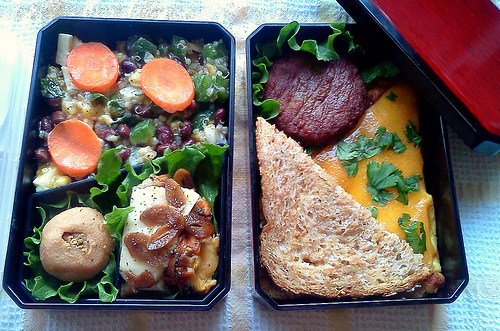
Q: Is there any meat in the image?
A: Yes, there is meat.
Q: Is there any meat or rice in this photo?
A: Yes, there is meat.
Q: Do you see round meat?
A: Yes, there is round meat.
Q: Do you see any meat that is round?
A: Yes, there is meat that is round.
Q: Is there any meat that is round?
A: Yes, there is meat that is round.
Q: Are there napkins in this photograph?
A: No, there are no napkins.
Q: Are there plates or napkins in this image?
A: No, there are no napkins or plates.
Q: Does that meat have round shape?
A: Yes, the meat is round.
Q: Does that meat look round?
A: Yes, the meat is round.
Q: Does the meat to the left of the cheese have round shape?
A: Yes, the meat is round.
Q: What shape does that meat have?
A: The meat has round shape.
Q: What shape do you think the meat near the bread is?
A: The meat is round.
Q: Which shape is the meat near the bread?
A: The meat is round.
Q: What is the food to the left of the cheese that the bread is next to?
A: The food is meat.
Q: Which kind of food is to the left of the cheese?
A: The food is meat.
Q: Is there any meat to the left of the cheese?
A: Yes, there is meat to the left of the cheese.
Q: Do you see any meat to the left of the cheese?
A: Yes, there is meat to the left of the cheese.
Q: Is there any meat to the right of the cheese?
A: No, the meat is to the left of the cheese.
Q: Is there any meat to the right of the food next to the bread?
A: No, the meat is to the left of the cheese.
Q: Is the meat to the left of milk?
A: No, the meat is to the left of the cheese.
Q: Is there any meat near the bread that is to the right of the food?
A: Yes, there is meat near the bread.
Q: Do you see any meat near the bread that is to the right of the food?
A: Yes, there is meat near the bread.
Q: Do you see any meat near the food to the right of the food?
A: Yes, there is meat near the bread.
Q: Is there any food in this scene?
A: Yes, there is food.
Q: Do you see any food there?
A: Yes, there is food.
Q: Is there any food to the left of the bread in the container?
A: Yes, there is food to the left of the bread.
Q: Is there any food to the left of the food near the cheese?
A: Yes, there is food to the left of the bread.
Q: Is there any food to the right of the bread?
A: No, the food is to the left of the bread.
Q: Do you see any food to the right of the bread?
A: No, the food is to the left of the bread.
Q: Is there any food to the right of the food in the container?
A: No, the food is to the left of the bread.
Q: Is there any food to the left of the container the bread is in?
A: Yes, there is food to the left of the container.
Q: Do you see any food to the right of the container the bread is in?
A: No, the food is to the left of the container.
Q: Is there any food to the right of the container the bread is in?
A: No, the food is to the left of the container.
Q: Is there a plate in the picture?
A: No, there are no plates.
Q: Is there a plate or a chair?
A: No, there are no plates or chairs.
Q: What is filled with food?
A: The container is filled with food.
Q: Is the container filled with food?
A: Yes, the container is filled with food.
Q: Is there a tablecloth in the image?
A: Yes, there is a tablecloth.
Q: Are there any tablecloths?
A: Yes, there is a tablecloth.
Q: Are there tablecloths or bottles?
A: Yes, there is a tablecloth.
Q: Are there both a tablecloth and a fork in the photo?
A: No, there is a tablecloth but no forks.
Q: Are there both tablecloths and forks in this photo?
A: No, there is a tablecloth but no forks.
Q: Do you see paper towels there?
A: No, there are no paper towels.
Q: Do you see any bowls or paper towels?
A: No, there are no paper towels or bowls.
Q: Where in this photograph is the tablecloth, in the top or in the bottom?
A: The tablecloth is in the bottom of the image.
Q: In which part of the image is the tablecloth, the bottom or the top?
A: The tablecloth is in the bottom of the image.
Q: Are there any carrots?
A: Yes, there is a carrot.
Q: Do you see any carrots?
A: Yes, there is a carrot.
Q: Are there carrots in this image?
A: Yes, there is a carrot.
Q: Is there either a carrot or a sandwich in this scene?
A: Yes, there is a carrot.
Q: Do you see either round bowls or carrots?
A: Yes, there is a round carrot.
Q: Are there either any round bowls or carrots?
A: Yes, there is a round carrot.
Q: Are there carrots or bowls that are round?
A: Yes, the carrot is round.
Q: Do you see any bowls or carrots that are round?
A: Yes, the carrot is round.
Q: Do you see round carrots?
A: Yes, there is a round carrot.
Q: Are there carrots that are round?
A: Yes, there is a carrot that is round.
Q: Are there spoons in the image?
A: No, there are no spoons.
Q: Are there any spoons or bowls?
A: No, there are no spoons or bowls.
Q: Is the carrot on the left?
A: Yes, the carrot is on the left of the image.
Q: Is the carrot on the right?
A: No, the carrot is on the left of the image.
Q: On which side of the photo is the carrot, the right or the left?
A: The carrot is on the left of the image.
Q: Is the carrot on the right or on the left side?
A: The carrot is on the left of the image.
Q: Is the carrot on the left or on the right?
A: The carrot is on the left of the image.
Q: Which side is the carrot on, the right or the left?
A: The carrot is on the left of the image.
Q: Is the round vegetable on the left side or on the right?
A: The carrot is on the left of the image.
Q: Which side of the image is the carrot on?
A: The carrot is on the left of the image.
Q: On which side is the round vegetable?
A: The carrot is on the left of the image.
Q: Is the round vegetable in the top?
A: Yes, the carrot is in the top of the image.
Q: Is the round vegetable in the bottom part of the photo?
A: No, the carrot is in the top of the image.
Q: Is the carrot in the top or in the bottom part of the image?
A: The carrot is in the top of the image.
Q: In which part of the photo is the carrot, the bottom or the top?
A: The carrot is in the top of the image.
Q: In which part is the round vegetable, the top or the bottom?
A: The carrot is in the top of the image.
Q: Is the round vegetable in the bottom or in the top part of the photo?
A: The carrot is in the top of the image.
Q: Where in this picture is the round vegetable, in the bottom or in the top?
A: The carrot is in the top of the image.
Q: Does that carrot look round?
A: Yes, the carrot is round.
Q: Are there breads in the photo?
A: Yes, there is a bread.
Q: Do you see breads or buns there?
A: Yes, there is a bread.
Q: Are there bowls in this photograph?
A: No, there are no bowls.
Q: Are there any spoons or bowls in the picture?
A: No, there are no bowls or spoons.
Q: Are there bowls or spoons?
A: No, there are no bowls or spoons.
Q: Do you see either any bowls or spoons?
A: No, there are no bowls or spoons.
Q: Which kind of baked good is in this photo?
A: The baked good is a bread.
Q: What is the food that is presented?
A: The food is a bread.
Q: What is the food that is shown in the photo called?
A: The food is a bread.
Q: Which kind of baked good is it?
A: The food is a bread.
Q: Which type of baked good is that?
A: This is a bread.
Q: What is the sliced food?
A: The food is a bread.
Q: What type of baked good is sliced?
A: The baked good is a bread.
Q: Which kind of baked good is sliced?
A: The baked good is a bread.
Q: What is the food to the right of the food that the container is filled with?
A: The food is a bread.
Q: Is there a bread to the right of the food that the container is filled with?
A: Yes, there is a bread to the right of the food.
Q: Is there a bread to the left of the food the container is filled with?
A: No, the bread is to the right of the food.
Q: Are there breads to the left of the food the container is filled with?
A: No, the bread is to the right of the food.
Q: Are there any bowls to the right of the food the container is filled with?
A: No, there is a bread to the right of the food.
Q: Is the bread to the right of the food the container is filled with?
A: Yes, the bread is to the right of the food.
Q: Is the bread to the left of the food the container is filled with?
A: No, the bread is to the right of the food.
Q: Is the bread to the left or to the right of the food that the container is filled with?
A: The bread is to the right of the food.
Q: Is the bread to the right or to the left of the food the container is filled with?
A: The bread is to the right of the food.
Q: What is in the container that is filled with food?
A: The bread is in the container.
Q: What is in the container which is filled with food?
A: The bread is in the container.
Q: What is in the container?
A: The bread is in the container.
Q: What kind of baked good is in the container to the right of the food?
A: The food is a bread.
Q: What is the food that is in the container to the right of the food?
A: The food is a bread.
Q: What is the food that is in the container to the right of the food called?
A: The food is a bread.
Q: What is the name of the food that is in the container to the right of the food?
A: The food is a bread.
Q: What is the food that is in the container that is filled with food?
A: The food is a bread.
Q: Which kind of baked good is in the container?
A: The food is a bread.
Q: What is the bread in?
A: The bread is in the container.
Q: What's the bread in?
A: The bread is in the container.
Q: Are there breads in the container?
A: Yes, there is a bread in the container.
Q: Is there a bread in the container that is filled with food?
A: Yes, there is a bread in the container.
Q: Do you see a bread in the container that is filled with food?
A: Yes, there is a bread in the container.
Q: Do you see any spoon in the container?
A: No, there is a bread in the container.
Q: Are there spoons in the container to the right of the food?
A: No, there is a bread in the container.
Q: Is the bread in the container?
A: Yes, the bread is in the container.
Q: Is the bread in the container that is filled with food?
A: Yes, the bread is in the container.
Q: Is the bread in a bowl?
A: No, the bread is in the container.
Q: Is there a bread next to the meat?
A: Yes, there is a bread next to the meat.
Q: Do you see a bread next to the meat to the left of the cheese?
A: Yes, there is a bread next to the meat.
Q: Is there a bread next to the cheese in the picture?
A: Yes, there is a bread next to the cheese.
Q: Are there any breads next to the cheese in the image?
A: Yes, there is a bread next to the cheese.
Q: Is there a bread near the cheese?
A: Yes, there is a bread near the cheese.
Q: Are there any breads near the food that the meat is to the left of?
A: Yes, there is a bread near the cheese.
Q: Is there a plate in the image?
A: No, there are no plates.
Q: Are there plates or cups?
A: No, there are no plates or cups.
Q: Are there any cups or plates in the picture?
A: No, there are no plates or cups.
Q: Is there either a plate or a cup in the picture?
A: No, there are no plates or cups.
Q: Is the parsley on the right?
A: Yes, the parsley is on the right of the image.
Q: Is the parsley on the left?
A: No, the parsley is on the right of the image.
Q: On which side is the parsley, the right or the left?
A: The parsley is on the right of the image.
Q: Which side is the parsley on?
A: The parsley is on the right of the image.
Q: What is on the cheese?
A: The parsley is on the cheese.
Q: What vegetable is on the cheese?
A: The vegetable is parsley.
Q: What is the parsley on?
A: The parsley is on the cheese.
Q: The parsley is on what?
A: The parsley is on the cheese.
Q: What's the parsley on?
A: The parsley is on the cheese.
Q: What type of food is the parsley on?
A: The parsley is on the cheese.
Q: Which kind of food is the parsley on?
A: The parsley is on the cheese.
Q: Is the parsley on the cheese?
A: Yes, the parsley is on the cheese.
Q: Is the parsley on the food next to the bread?
A: Yes, the parsley is on the cheese.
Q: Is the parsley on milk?
A: No, the parsley is on the cheese.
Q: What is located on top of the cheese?
A: The parsley is on top of the cheese.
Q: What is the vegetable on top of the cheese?
A: The vegetable is parsley.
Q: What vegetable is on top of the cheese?
A: The vegetable is parsley.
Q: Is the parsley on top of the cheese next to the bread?
A: Yes, the parsley is on top of the cheese.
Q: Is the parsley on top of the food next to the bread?
A: Yes, the parsley is on top of the cheese.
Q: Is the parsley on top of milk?
A: No, the parsley is on top of the cheese.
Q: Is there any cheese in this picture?
A: Yes, there is cheese.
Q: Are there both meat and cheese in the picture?
A: Yes, there are both cheese and meat.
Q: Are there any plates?
A: No, there are no plates.